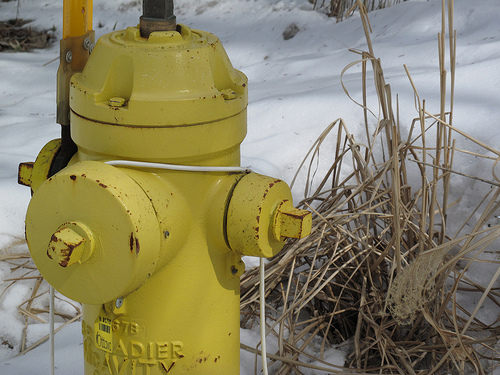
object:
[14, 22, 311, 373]
fire hydrant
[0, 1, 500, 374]
snow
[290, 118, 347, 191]
stalk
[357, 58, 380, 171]
stalk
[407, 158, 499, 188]
stalk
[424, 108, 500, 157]
stalk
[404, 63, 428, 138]
stalk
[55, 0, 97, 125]
pole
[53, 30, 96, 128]
panel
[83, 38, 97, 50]
screw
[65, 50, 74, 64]
screw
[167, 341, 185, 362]
lettering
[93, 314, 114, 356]
sticker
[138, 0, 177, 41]
plug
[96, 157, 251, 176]
cord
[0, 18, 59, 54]
debris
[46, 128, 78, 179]
base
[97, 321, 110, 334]
bar code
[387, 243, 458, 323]
plant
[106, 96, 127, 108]
bolt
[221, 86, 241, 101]
bolt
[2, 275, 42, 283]
grass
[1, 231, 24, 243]
grass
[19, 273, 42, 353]
grass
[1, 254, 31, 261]
grass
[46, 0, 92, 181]
wrench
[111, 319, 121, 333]
numbers